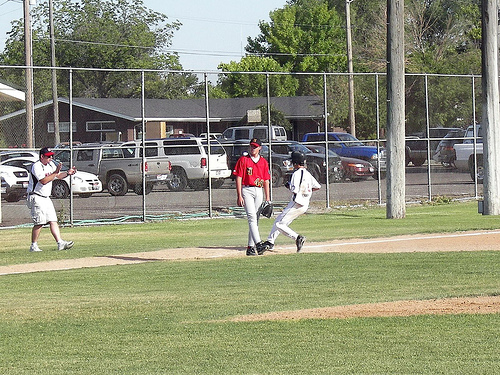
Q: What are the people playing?
A: Baseball.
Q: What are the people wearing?
A: Baseball uniforms.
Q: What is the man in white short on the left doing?
A: Clapping.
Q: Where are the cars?
A: In the parking lot.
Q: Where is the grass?
A: On the baseball field.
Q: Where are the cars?
A: Behind the fence.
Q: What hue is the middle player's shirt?
A: Red.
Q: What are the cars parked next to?
A: Building.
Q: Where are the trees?
A: Behind the building.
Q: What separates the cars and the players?
A: Fence.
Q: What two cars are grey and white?
A: The truck and SUV.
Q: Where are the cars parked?
A: At the parking lot.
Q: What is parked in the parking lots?
A: Cars.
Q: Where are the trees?
A: Behind a building.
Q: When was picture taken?
A: Daytime.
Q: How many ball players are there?
A: Two.